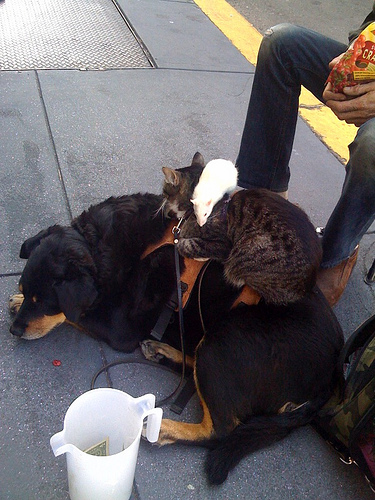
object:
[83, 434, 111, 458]
bill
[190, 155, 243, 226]
mouse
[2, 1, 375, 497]
sidewalk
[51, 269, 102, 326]
ear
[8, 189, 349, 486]
animal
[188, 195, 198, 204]
ear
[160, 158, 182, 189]
ear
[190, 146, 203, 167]
ear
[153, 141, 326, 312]
animal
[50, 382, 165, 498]
pitcher